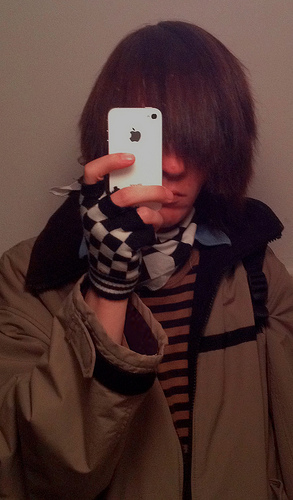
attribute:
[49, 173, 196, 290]
bandanna — black, white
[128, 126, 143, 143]
apple logo — apple 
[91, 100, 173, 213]
iphone — white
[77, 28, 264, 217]
hair — long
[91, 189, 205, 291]
scarf — checkered, black, white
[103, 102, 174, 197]
iphone — white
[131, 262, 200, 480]
t-shirt — brown, black, striped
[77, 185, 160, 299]
glove — black, white, checkerboard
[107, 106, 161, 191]
iphone — white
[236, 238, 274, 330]
strap — black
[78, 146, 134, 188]
finger — pointer 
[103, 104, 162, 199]
apple phone — white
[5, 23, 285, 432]
man — young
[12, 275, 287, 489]
jacket — brown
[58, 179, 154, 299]
gloves — white, black, fingerless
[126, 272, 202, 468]
shirt — red, black, striped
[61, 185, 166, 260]
gloves — white, black, checkered, fingerless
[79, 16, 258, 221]
hair — long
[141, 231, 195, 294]
scarf — black, white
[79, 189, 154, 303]
glove — black, checkered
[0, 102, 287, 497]
man — young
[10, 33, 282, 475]
man — young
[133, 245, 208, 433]
shirt — striped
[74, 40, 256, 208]
hair — mop top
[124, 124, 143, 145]
logo — apple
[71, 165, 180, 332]
hand — gloved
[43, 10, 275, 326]
man — young